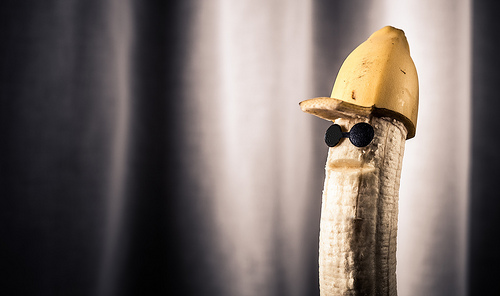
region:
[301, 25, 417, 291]
banana with banana peel hat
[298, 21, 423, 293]
banana made to look like a construction worker with a hard hat and glasses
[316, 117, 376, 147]
man made black sunglasses on peeled banana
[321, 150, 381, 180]
dent in peeled banana made to look like a mouth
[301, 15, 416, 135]
end of banana peel carved out and made to look like a hat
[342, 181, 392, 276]
white fruit striation on side of banana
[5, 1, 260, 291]
grey and white curtain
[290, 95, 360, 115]
brim of man made banana hat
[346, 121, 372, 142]
round black lens on man made sunglasses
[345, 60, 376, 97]
brown marks on banana peel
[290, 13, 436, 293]
A banana is in the foreground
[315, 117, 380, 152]
Banana is wearing eye dots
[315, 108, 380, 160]
Banana's eye dots are black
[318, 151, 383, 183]
Banana is sliced to look like a mouth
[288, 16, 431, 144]
Banana is wearing a cap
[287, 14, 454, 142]
Banana's cap is yellow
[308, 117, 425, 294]
Banana's skin is peeled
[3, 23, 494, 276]
Background is gray in color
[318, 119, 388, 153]
Eye dots are connected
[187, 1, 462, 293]
Light is reflecting off surface in the background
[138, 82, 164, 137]
black spot in the back ground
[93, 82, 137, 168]
shiny silver line on wall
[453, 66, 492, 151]
black edge on wall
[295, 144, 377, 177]
small mouth on the banana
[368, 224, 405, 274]
line in the banana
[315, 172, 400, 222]
small grooves in the tan banana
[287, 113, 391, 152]
pair of sun glasses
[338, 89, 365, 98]
brown spot on yellow hat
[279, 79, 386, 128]
shade on the yellow banana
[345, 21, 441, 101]
yellow banana hat with point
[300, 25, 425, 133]
a yellow banana peel hat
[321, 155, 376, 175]
a cut banana mouth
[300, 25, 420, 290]
a banana person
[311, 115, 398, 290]
a darkening banana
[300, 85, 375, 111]
the bill of a banana peel cap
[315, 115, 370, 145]
two black eyes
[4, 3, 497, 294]
a wavy white background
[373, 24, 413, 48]
the tip of a banana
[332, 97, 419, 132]
a browning cut edge of a banana peel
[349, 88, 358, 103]
a brown spot on a banana peel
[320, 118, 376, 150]
banana is wearing sunglasses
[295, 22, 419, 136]
banana is wearing peel cap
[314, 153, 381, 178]
banana has mouth open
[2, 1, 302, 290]
curtain in background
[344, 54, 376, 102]
brown spotson peel cap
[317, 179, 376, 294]
no demarcation between banana's chin and neck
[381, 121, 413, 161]
banana has no ear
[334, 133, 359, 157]
banana has no nose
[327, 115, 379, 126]
banana has no eyebrows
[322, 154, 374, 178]
banana has no teeth